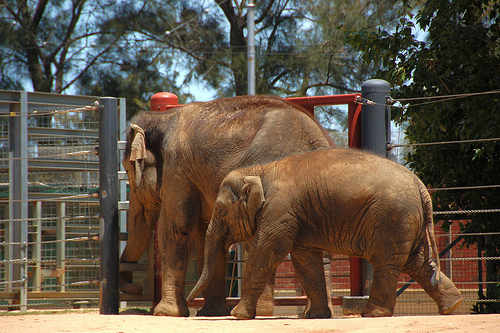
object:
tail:
[416, 175, 443, 282]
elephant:
[185, 148, 465, 319]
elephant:
[116, 95, 334, 316]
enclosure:
[2, 87, 499, 318]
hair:
[189, 96, 267, 121]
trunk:
[115, 176, 161, 296]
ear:
[126, 124, 147, 189]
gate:
[146, 90, 363, 312]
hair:
[281, 146, 368, 169]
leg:
[292, 246, 329, 307]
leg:
[403, 249, 458, 302]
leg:
[195, 223, 229, 305]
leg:
[156, 168, 198, 303]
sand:
[201, 145, 463, 310]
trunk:
[185, 204, 231, 305]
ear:
[244, 175, 266, 222]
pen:
[1, 66, 498, 331]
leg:
[360, 240, 409, 314]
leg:
[240, 230, 294, 307]